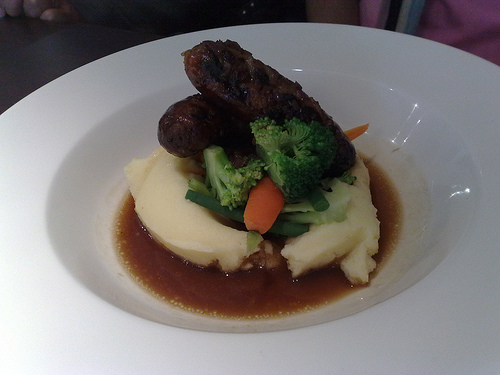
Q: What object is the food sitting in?
A: Bowl.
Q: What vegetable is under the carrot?
A: Green beans.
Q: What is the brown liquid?
A: Gravy.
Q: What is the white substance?
A: Potato.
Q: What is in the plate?
A: Meat and potatoes.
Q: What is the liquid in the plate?
A: Sauce.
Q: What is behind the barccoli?
A: Two cook sausages.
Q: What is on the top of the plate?
A: Meat.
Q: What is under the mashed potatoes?
A: Gravy Sauce.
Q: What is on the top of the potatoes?
A: Steamed potatoes.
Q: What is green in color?
A: Broccoli Leaves.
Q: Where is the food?
A: On a plate.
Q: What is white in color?
A: A plate.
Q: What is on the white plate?
A: A meal.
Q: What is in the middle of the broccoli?
A: A carrot.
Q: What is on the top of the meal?
A: Meat.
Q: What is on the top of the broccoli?
A: Meat.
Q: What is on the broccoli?
A: Brown meat.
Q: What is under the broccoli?
A: Mashed potatoes.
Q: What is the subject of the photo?
A: A shallow bowl of food.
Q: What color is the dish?
A: White.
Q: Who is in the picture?
A: No one.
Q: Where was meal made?
A: In kitchen.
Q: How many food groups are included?
A: 4.